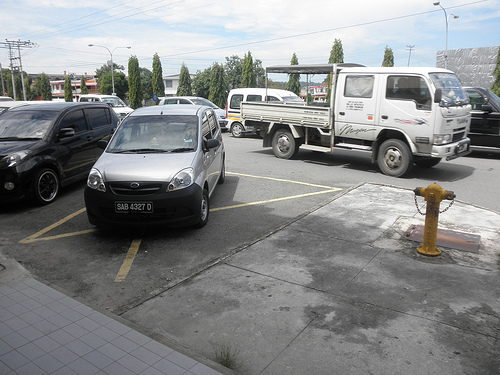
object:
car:
[158, 96, 226, 129]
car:
[78, 94, 135, 121]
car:
[0, 101, 120, 206]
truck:
[462, 86, 500, 149]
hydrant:
[412, 184, 456, 256]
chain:
[414, 195, 455, 216]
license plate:
[115, 201, 154, 213]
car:
[84, 104, 226, 232]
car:
[0, 95, 15, 101]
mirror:
[58, 128, 75, 139]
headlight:
[0, 150, 32, 171]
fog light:
[4, 182, 15, 190]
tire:
[377, 138, 414, 177]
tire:
[271, 128, 299, 159]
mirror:
[434, 88, 442, 103]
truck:
[240, 66, 474, 177]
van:
[225, 87, 305, 138]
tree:
[151, 51, 165, 105]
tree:
[128, 54, 144, 109]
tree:
[174, 60, 194, 104]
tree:
[208, 60, 227, 109]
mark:
[268, 211, 386, 262]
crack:
[284, 226, 370, 246]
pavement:
[113, 182, 500, 375]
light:
[87, 43, 132, 95]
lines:
[225, 171, 343, 190]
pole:
[18, 47, 27, 101]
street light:
[432, 0, 459, 69]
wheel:
[230, 122, 245, 138]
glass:
[105, 115, 199, 153]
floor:
[0, 131, 500, 375]